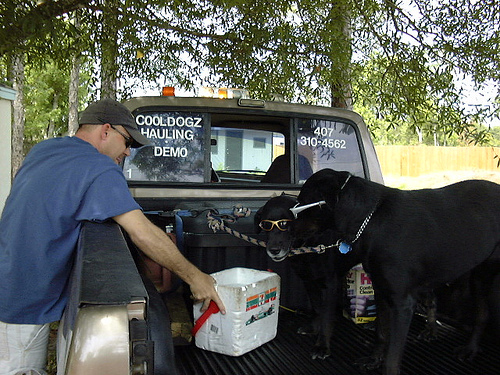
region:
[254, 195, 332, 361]
black dog wearing gold sunglasses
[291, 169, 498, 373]
black dog wearing white sunglasses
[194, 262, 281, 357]
styrofoam cooler with no top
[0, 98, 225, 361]
man giving the dogs a cooler filled with water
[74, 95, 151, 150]
hat the man is wearing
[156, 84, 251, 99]
lights on top of the truck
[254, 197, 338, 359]
the dog has gold glasses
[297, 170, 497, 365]
the dog has white glasses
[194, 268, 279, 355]
the cooler is white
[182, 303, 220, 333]
the handle is red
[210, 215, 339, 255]
the leash is green and white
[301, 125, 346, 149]
the phone number 407-310-4562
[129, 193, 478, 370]
the truck liner is black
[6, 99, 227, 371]
the man is wering black sunglasses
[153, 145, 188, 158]
the word demo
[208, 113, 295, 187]
the window is open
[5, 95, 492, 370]
open styrofoam cooler between man and dogs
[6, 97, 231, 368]
man leaning over side of truck holding cooler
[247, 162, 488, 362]
black dogs wearing gold and silver sunglasses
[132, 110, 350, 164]
name and telephone number for company on back window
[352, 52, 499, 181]
tree in back of wooden fence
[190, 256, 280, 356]
cooler with stickers and red handle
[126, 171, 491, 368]
tethered dogs standing in back of truck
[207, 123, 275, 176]
white house with black door and windows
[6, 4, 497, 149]
blue sky through lacy tree leaves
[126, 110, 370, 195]
middle window open in back of truck cab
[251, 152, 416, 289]
Two dogs in the truck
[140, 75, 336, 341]
A pickup truck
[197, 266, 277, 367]
A box in the truck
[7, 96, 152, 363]
A man in the photo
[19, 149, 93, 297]
A blue shirt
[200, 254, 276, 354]
A white box on the truck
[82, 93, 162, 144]
A black hat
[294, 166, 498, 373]
a black dog wearing white sunglasses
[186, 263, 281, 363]
a mostly white cooler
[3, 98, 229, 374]
a man wearing a blue shirt and hat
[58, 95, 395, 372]
a platinum color pickup truck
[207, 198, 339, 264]
a blue and white rope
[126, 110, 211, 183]
a window with name of business painted on it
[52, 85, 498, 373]
two black dogs in back of pickup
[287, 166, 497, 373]
a black dog wearing white sunglasses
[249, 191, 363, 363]
a black dog wearing brown sunglasses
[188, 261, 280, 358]
a white Styrofoam container of water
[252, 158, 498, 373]
black dogs in the back of the truck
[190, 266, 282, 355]
a white foam cooler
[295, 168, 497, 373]
a large black dog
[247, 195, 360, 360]
a large black dog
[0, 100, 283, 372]
a man holding a cooler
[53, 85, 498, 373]
an open bed pickup truck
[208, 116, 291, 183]
an open rear window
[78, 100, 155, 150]
a man's brown hat